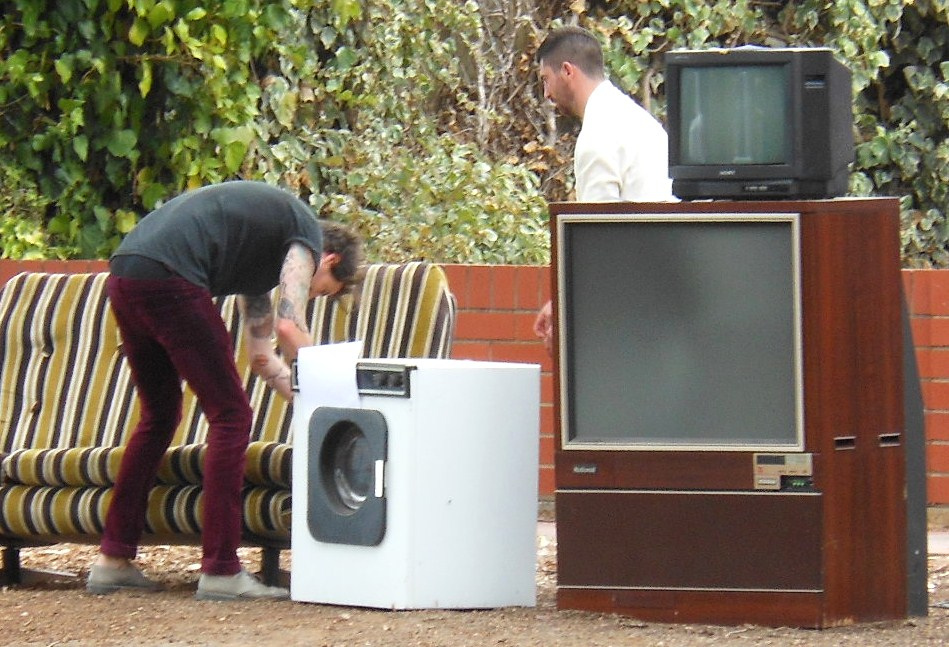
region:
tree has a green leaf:
[134, 61, 150, 94]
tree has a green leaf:
[104, 129, 137, 158]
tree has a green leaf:
[69, 133, 89, 162]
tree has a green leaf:
[63, 106, 86, 131]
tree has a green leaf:
[89, 204, 109, 233]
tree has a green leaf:
[114, 208, 138, 233]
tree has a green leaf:
[175, 18, 206, 57]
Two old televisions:
[540, 41, 942, 637]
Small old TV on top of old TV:
[542, 43, 947, 635]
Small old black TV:
[654, 44, 860, 202]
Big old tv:
[539, 192, 936, 633]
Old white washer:
[286, 341, 546, 613]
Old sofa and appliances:
[2, 37, 936, 630]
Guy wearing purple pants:
[77, 178, 368, 602]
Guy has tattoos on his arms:
[77, 178, 368, 602]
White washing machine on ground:
[287, 328, 563, 645]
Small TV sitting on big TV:
[526, 16, 935, 645]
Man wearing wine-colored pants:
[73, 138, 369, 616]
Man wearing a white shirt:
[509, 8, 664, 204]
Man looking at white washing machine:
[62, 76, 560, 641]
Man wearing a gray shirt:
[73, 102, 369, 629]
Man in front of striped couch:
[0, 152, 456, 622]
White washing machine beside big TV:
[281, 188, 933, 631]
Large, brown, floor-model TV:
[535, 195, 932, 634]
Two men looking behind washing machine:
[82, 1, 692, 628]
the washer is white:
[275, 362, 543, 607]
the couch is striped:
[3, 262, 444, 539]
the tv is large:
[542, 188, 905, 623]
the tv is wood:
[551, 191, 898, 619]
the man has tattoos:
[243, 254, 316, 347]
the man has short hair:
[321, 220, 369, 310]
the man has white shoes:
[87, 571, 283, 596]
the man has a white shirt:
[568, 68, 673, 208]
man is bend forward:
[64, 162, 379, 616]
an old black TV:
[643, 24, 884, 211]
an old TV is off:
[518, 186, 939, 626]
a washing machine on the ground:
[274, 335, 565, 638]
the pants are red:
[83, 258, 259, 583]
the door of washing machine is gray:
[284, 392, 406, 557]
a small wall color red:
[433, 231, 582, 521]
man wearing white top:
[510, 7, 705, 238]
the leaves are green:
[7, 18, 275, 161]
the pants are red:
[105, 291, 259, 577]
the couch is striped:
[21, 272, 412, 514]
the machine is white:
[313, 352, 543, 640]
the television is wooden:
[553, 202, 906, 626]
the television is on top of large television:
[643, 50, 895, 257]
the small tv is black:
[653, 43, 873, 202]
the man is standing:
[530, 31, 661, 224]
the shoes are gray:
[92, 547, 294, 610]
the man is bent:
[142, 199, 429, 425]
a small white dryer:
[289, 337, 535, 623]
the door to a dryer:
[306, 404, 400, 543]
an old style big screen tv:
[546, 196, 912, 629]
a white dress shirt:
[573, 80, 677, 226]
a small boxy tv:
[670, 39, 854, 197]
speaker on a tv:
[548, 476, 813, 604]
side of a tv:
[794, 203, 907, 643]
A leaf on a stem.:
[217, 123, 246, 146]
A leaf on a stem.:
[231, 122, 255, 149]